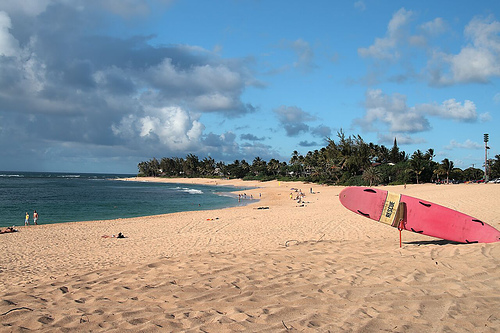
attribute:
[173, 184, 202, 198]
waves — rolling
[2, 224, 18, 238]
person — laying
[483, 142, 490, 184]
metal post — large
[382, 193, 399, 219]
writing — black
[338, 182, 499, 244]
surfboard — red, pink, yellow, sticking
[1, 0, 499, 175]
sky — blue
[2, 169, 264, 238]
water — blue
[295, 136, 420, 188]
trees — green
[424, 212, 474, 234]
board — red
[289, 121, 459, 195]
leaves — green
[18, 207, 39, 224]
people — walking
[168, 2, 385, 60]
sky — blue